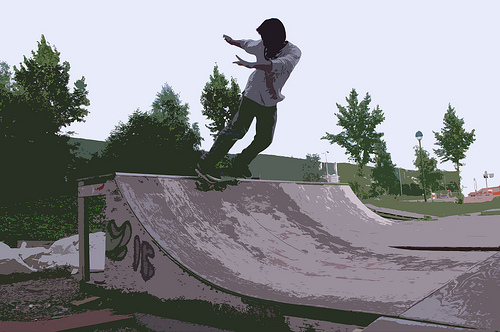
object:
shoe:
[223, 150, 274, 177]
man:
[191, 13, 302, 178]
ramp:
[72, 165, 498, 330]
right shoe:
[176, 160, 232, 194]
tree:
[434, 93, 488, 198]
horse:
[95, 166, 427, 303]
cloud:
[0, 0, 500, 159]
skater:
[190, 10, 310, 189]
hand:
[226, 51, 262, 73]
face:
[253, 31, 282, 56]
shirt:
[228, 37, 300, 104]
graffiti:
[98, 207, 161, 292]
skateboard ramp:
[68, 160, 498, 328]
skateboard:
[191, 155, 256, 191]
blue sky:
[0, 1, 498, 170]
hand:
[221, 26, 238, 50]